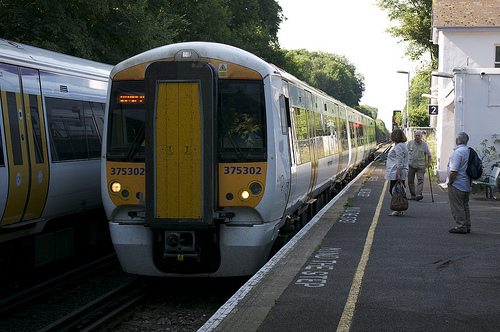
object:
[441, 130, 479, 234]
man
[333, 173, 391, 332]
line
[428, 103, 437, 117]
track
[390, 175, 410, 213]
backpack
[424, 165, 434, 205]
cane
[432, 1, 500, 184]
building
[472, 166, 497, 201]
abench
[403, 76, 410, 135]
post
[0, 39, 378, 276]
two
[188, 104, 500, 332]
station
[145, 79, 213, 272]
door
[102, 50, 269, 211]
front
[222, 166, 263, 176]
blue numbers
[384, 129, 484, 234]
three people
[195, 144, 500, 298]
platform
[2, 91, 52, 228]
doors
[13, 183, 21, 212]
yellow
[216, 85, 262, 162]
reflection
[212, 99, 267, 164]
window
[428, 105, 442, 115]
number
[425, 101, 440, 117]
sign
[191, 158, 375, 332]
white line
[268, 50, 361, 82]
green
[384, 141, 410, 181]
shirt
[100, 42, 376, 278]
train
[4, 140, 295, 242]
tracks